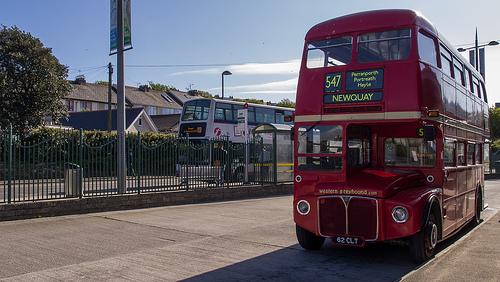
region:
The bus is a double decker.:
[302, 14, 491, 246]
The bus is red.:
[287, 18, 487, 239]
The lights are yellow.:
[315, 67, 397, 112]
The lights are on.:
[313, 67, 389, 109]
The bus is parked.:
[287, 11, 497, 251]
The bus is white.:
[183, 98, 290, 194]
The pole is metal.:
[106, 9, 139, 190]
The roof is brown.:
[60, 77, 206, 116]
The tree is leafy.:
[0, 25, 67, 156]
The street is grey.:
[29, 184, 291, 277]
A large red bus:
[284, 18, 461, 271]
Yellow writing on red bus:
[319, 58, 391, 111]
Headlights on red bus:
[291, 186, 418, 233]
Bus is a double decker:
[293, 23, 442, 277]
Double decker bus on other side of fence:
[168, 90, 251, 189]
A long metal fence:
[68, 132, 223, 192]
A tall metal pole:
[106, 8, 148, 203]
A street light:
[212, 62, 237, 94]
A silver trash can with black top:
[59, 155, 91, 209]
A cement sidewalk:
[409, 258, 464, 279]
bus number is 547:
[324, 74, 343, 90]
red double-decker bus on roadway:
[296, 10, 489, 254]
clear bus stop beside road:
[251, 119, 293, 184]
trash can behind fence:
[63, 160, 86, 194]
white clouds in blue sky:
[184, 65, 291, 99]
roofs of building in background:
[60, 77, 258, 115]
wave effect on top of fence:
[4, 131, 274, 153]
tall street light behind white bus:
[220, 68, 232, 97]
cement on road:
[53, 224, 134, 278]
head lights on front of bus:
[295, 196, 408, 225]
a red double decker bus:
[290, 5, 493, 256]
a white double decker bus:
[172, 95, 302, 190]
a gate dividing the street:
[16, 127, 281, 193]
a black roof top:
[58, 103, 171, 140]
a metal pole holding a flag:
[104, 0, 138, 188]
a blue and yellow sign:
[322, 70, 385, 110]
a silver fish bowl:
[317, 192, 387, 242]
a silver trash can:
[55, 155, 91, 203]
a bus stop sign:
[232, 105, 254, 135]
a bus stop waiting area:
[251, 116, 296, 193]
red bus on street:
[301, 19, 434, 214]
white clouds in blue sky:
[16, 0, 41, 22]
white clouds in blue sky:
[54, 21, 75, 38]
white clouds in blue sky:
[54, 15, 99, 42]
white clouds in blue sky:
[154, 22, 190, 66]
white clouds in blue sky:
[187, 20, 227, 64]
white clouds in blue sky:
[221, 7, 281, 47]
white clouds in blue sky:
[249, 41, 289, 109]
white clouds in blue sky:
[439, 4, 471, 27]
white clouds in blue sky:
[166, 35, 212, 69]